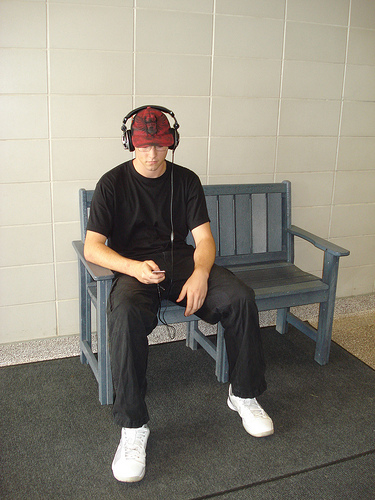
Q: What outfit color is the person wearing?
A: Black.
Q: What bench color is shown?
A: Blue.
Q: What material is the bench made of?
A: Wood.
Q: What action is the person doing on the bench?
A: Sitting.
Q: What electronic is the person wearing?
A: Headphones.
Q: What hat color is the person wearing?
A: Red.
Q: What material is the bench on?
A: Rugs.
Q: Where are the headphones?
A: On the man's head.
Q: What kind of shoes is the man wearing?
A: White tennis shoes.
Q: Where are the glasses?
A: On the man's face.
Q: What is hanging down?
A: Cord.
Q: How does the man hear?
A: Through headphones.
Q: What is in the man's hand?
A: Cell phone.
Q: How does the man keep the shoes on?
A: Tied.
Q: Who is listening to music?
A: The man on the bench.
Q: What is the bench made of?
A: Wood.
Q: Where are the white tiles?
A: On the wall.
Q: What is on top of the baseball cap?
A: Headphones.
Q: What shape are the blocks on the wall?
A: Square.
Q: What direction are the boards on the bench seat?
A: Horizontal.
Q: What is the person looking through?
A: Eyeglasses.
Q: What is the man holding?
A: Electronic device.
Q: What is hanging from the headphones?
A: Black cord.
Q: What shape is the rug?
A: Rectangle.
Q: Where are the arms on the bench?
A: Outside edges.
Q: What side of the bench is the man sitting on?
A: The left side.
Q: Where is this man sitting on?
A: A bench.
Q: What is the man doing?
A: Listening to music.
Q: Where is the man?
A: On a bench.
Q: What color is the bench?
A: Blue.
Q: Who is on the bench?
A: A man.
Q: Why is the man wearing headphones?
A: To hear the music better.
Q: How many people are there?
A: 1.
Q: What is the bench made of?
A: Wood.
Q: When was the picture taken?
A: Daytime.